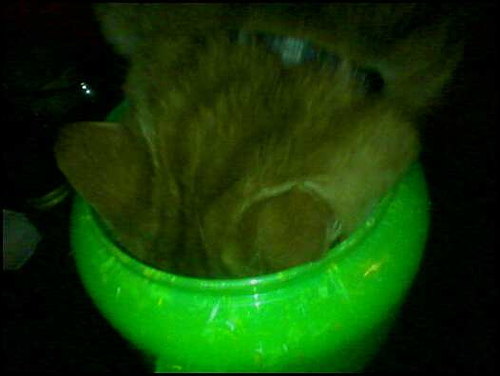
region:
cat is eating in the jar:
[62, 72, 399, 326]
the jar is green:
[67, 188, 383, 373]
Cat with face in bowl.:
[54, 0, 491, 375]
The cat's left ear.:
[51, 126, 150, 211]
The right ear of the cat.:
[212, 169, 334, 256]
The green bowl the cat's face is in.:
[60, 179, 441, 364]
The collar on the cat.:
[226, 20, 382, 95]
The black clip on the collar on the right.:
[362, 67, 389, 96]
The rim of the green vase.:
[75, 195, 395, 287]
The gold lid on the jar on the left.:
[30, 191, 71, 206]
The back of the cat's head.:
[136, 63, 324, 177]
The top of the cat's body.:
[95, 0, 457, 82]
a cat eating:
[50, 65, 405, 292]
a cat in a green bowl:
[40, 0, 475, 365]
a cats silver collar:
[240, 36, 390, 106]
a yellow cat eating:
[25, 10, 496, 370]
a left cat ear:
[240, 171, 340, 286]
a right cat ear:
[45, 110, 165, 236]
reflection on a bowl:
[240, 280, 280, 315]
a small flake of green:
[360, 250, 390, 285]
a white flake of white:
[197, 295, 237, 325]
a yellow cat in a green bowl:
[62, 0, 477, 368]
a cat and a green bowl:
[5, 25, 477, 355]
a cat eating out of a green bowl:
[20, 58, 450, 303]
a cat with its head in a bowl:
[15, 35, 477, 343]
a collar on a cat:
[130, 24, 402, 105]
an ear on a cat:
[44, 111, 166, 225]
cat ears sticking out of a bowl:
[57, 103, 342, 278]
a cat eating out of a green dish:
[35, 44, 457, 374]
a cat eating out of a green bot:
[40, 74, 481, 371]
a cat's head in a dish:
[38, 77, 468, 374]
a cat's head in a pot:
[30, 67, 472, 371]